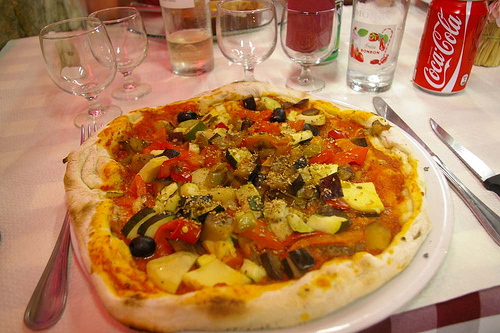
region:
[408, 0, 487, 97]
a can of soda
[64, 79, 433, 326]
a large vegetable pizza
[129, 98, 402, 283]
the vegetables have pepper on them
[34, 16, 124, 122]
a clear glass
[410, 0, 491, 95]
the soda can is red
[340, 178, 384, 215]
a piece of vegetable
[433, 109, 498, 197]
a black handled silver knife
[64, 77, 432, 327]
the pizza has vegetables on it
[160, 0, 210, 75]
a glass of ice tea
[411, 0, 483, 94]
the coca cola can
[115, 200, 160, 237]
zucchini topping on a pizza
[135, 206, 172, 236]
zucchini topping on a pizza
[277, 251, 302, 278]
zucchini topping on a pizza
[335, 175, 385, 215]
zucchini topping on a pizza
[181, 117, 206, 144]
zucchini topping on a pizza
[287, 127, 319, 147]
zucchini topping on a pizza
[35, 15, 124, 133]
wine glass on a table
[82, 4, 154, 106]
wine glass on a table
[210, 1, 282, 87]
wine glass on a table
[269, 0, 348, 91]
wine glass on a table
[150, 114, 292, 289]
A pizza with pineapples on it.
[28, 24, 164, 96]
Glasses sitting on the table.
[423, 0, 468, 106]
A can of coke on the table.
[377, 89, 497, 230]
Two knives on the table.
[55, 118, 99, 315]
A fork on the side of the pizza.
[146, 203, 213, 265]
The pizza has red peppers on it.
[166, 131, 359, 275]
The pizza has vegetables toppings.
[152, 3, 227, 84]
A glass of water on the table.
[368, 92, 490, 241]
A butter knife next to the plate.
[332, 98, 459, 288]
The plate is white.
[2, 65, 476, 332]
vegitables on thick crust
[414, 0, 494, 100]
can of coca cola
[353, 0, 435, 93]
empty wine bottle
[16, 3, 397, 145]
four empty wine glasses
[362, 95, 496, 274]
two knives on table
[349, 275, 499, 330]
red and white gingham table cloth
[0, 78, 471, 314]
fork on left side of plate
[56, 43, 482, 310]
chopped veggies with spices on top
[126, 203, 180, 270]
grilled zuchini and olive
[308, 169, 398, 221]
large piece of yellow squash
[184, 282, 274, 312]
crust on deep dish pizza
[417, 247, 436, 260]
black spot on white plate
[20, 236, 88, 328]
edge of silver fork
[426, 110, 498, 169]
silver blade on knife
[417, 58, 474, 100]
red soda can on table top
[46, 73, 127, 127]
clear drinking wine glass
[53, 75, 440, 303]
pizza on white plate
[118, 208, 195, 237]
pieces of green cucumber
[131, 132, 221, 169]
red and yellow peppers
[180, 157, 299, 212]
broken pieces of broccoli on pizza